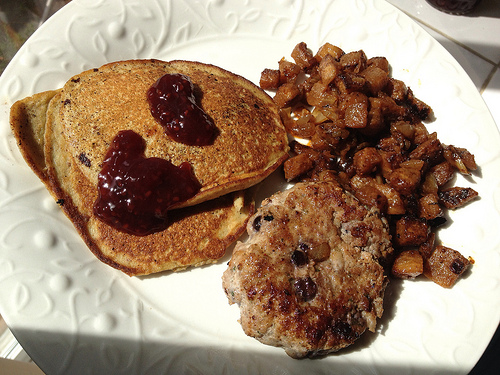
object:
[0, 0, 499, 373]
plate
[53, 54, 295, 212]
pancake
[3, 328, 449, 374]
shadow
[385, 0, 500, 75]
tile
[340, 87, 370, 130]
hashbrown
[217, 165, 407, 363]
sausage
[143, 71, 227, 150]
jam